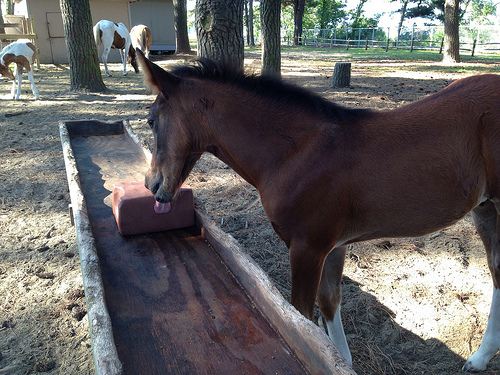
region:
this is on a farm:
[20, 19, 392, 289]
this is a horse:
[146, 66, 409, 234]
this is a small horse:
[153, 47, 433, 272]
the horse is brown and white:
[168, 70, 397, 247]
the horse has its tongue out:
[87, 147, 244, 306]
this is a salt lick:
[102, 173, 157, 235]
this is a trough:
[123, 252, 335, 368]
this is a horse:
[175, 40, 489, 230]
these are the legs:
[281, 246, 346, 303]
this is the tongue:
[153, 197, 170, 215]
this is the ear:
[128, 51, 168, 98]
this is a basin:
[196, 307, 282, 360]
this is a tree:
[190, 1, 239, 41]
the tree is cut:
[333, 60, 353, 82]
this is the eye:
[142, 114, 160, 132]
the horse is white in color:
[95, 16, 124, 55]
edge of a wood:
[240, 235, 289, 319]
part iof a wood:
[187, 327, 224, 358]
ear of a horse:
[133, 46, 181, 95]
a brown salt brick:
[110, 178, 200, 236]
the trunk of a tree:
[58, 5, 105, 89]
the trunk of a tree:
[193, 1, 241, 69]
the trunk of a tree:
[258, 1, 280, 81]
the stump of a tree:
[332, 61, 352, 90]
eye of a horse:
[146, 114, 153, 126]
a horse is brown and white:
[95, 18, 132, 73]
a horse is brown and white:
[0, 38, 40, 102]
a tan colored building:
[26, 1, 178, 62]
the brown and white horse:
[133, 47, 497, 372]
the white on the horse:
[322, 285, 499, 372]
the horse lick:
[112, 183, 194, 236]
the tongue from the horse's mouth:
[153, 199, 171, 214]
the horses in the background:
[0, 18, 151, 98]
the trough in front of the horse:
[55, 117, 358, 374]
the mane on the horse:
[168, 56, 374, 121]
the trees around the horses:
[0, 0, 497, 96]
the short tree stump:
[330, 60, 350, 87]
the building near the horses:
[0, 0, 177, 64]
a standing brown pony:
[129, 43, 499, 373]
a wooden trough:
[56, 117, 356, 372]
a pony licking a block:
[112, 47, 497, 371]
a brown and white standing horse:
[0, 40, 39, 97]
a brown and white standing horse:
[94, 17, 131, 73]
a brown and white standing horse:
[130, 23, 150, 58]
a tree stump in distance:
[330, 62, 351, 88]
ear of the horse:
[129, 49, 166, 94]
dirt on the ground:
[480, 289, 489, 326]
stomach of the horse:
[415, 220, 462, 243]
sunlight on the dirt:
[388, 277, 463, 312]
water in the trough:
[182, 309, 237, 336]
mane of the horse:
[216, 68, 271, 84]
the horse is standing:
[0, 37, 44, 102]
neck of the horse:
[215, 145, 250, 184]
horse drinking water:
[128, 46, 498, 371]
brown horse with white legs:
[124, 51, 497, 371]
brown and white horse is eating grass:
[91, 13, 137, 83]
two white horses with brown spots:
[0, 13, 138, 114]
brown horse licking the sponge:
[108, 47, 498, 369]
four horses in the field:
[1, 5, 499, 367]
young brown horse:
[111, 40, 498, 372]